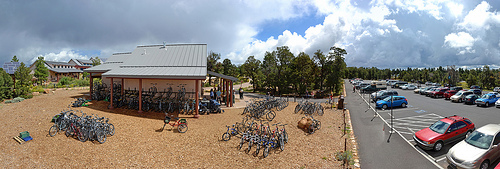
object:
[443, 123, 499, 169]
car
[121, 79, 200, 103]
wall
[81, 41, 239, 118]
building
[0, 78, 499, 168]
ground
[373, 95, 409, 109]
car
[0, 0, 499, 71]
sky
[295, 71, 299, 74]
leaves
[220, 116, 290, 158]
rack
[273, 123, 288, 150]
bikes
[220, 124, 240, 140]
bikes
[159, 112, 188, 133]
bike